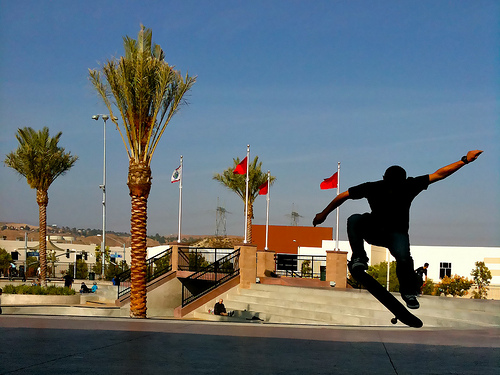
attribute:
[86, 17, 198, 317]
tree — palm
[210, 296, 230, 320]
guy — seated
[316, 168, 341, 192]
flag — red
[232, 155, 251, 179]
flag — flying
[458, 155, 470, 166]
watch — black, dark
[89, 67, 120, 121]
leaves — green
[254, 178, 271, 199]
flag — red, white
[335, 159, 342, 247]
pole — white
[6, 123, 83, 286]
tree — palm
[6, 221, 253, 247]
hill — brown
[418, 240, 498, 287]
building — white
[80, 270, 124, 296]
people — seated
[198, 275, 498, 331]
stair — rowed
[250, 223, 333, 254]
roof — red, brown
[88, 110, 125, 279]
light — tall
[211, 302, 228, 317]
shirt — black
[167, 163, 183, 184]
flag — white, red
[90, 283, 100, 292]
shirt — blue